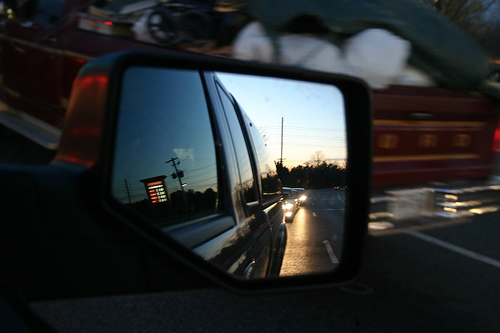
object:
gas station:
[139, 175, 170, 203]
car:
[281, 188, 296, 222]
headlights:
[286, 203, 292, 209]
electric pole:
[172, 156, 192, 213]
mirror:
[113, 68, 344, 282]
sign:
[146, 182, 166, 203]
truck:
[2, 4, 498, 233]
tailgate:
[370, 83, 496, 185]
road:
[280, 189, 347, 277]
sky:
[216, 74, 347, 171]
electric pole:
[125, 179, 132, 205]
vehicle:
[1, 55, 373, 333]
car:
[292, 188, 308, 206]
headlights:
[299, 195, 307, 201]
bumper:
[368, 176, 498, 236]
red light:
[334, 187, 337, 189]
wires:
[112, 157, 249, 200]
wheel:
[145, 6, 189, 43]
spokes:
[151, 17, 173, 37]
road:
[30, 214, 495, 333]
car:
[113, 64, 288, 281]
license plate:
[375, 119, 487, 161]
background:
[2, 1, 500, 332]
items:
[74, 2, 494, 91]